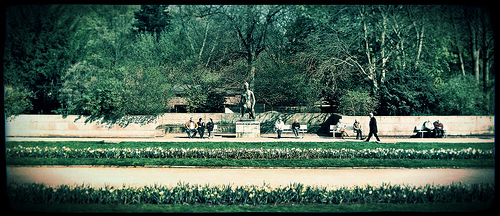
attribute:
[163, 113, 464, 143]
people — sitting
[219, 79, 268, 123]
statue — standing, green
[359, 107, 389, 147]
person — walking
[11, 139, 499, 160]
flowers — white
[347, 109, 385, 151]
man — walking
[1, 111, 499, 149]
wall — concrete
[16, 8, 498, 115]
trees — green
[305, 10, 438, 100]
branches — brown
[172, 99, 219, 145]
people — sitting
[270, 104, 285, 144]
person — sitting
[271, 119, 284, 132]
shirt — white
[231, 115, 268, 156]
pedestal — marble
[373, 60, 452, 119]
leaves — green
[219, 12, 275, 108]
tree — tall